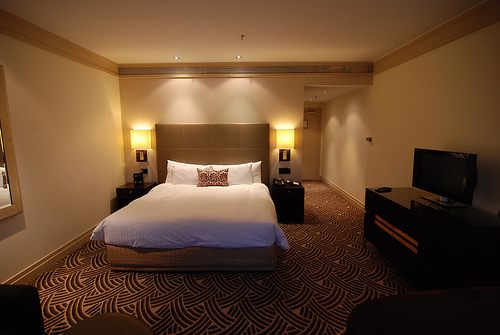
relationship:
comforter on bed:
[79, 178, 297, 256] [81, 118, 301, 267]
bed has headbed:
[81, 118, 301, 267] [146, 116, 273, 185]